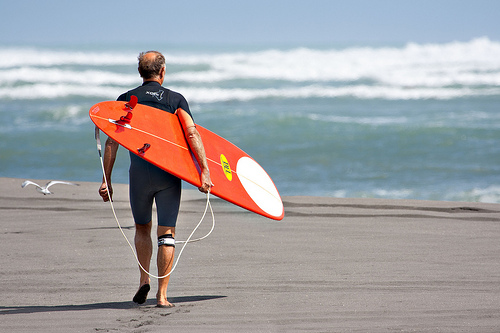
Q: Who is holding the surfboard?
A: The man.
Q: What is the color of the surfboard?
A: Orange.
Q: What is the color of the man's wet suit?
A: Black.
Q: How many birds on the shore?
A: One.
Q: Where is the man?
A: On the beach.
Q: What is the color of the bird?
A: White.